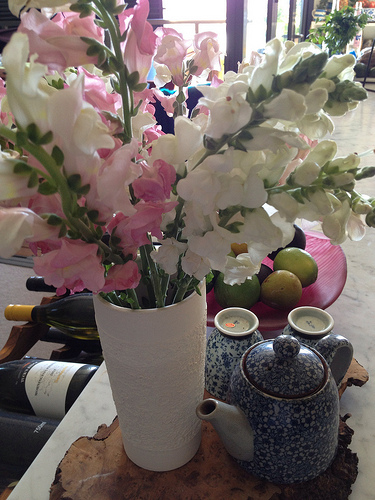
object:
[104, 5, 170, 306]
stem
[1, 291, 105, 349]
bottle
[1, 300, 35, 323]
cap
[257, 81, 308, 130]
flowers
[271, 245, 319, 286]
fruit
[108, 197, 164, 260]
flowers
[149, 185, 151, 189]
petals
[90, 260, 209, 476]
vase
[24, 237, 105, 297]
flower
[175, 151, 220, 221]
flower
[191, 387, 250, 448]
spout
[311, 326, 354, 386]
handle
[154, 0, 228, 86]
window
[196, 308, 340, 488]
teacups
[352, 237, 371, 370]
counter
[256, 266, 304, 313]
fruit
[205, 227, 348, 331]
dish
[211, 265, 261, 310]
fruit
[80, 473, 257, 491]
mat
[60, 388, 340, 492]
wood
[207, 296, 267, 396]
cups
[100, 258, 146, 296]
flowers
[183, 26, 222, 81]
flowers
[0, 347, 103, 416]
bottles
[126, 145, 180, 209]
flowers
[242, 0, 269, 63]
windows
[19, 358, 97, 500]
table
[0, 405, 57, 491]
wine bottle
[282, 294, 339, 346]
candle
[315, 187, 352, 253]
flowers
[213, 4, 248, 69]
column